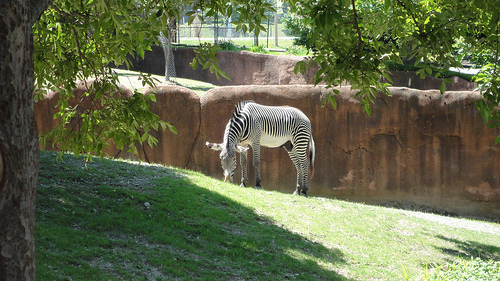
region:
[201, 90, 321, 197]
White and black zebra standing on all four legs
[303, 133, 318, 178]
Thin black and white tail of a zebra that grows thick at the end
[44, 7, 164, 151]
Light green leaves hanging down on thin branches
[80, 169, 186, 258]
Green and gray hill of grass bathed in shadow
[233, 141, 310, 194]
Legs of a zebra with thin black stripes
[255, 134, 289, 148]
White underbelly of a zebra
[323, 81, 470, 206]
Tall wooden wall with light streaks down it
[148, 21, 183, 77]
Tall gray tree trunk beyond a rock wall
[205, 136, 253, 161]
Ears on a zebra extending on either side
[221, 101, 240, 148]
Black and white fluffy mane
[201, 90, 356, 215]
zebra grazing on grass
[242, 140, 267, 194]
leg of the zebra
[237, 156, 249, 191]
leg of the zebra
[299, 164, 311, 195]
leg of the zebra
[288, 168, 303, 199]
leg of the zebra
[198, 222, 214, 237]
patch of green grass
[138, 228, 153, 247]
patch of green grass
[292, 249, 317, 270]
patch of green grass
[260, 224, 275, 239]
patch of green grass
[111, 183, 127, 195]
patch of green grass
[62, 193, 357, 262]
The grass is green and short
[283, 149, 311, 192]
The back legs of the zebra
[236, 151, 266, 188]
The front legs of the zebra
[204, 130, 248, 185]
The head of the zebra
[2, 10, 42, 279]
The tree trunk is the color brown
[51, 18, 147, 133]
The leaves are short and green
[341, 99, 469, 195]
The wall is made of cement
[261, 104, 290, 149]
The stomach of the zebra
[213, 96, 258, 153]
The mane of the zebra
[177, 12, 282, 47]
The gate is made of metal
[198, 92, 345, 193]
a zebra standing in a field.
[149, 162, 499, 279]
a lawn with light on it.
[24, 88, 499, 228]
A long fence near a zebra.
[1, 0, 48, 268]
a tall brown tree trunk.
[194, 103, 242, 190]
The head of a zebra.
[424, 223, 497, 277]
a shadow on the grass.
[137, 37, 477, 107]
a short rock wall.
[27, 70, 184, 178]
a tree branch with leaves.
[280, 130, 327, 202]
legs on a zebra.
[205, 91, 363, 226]
the zebra is eating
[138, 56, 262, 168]
a brown stone wall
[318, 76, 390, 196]
a brown stone wall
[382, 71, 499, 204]
a brown stone wall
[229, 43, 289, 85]
a brown stone wall